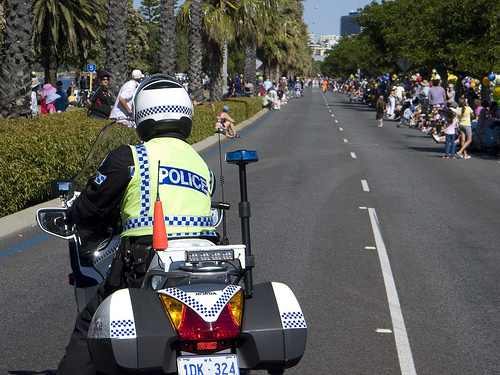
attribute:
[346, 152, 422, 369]
lines — white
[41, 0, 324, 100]
palms — grouped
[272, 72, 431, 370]
street — empty, grey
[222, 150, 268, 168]
light — blue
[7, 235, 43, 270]
line — blue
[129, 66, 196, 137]
helmet — white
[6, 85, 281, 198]
bushes — green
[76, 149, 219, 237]
jacket — yellow, green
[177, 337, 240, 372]
license — white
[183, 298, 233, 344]
light — red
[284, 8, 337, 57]
buildings — tall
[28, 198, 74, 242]
rearview mirror — white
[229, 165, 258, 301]
pole — black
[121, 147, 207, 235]
vest — checkered